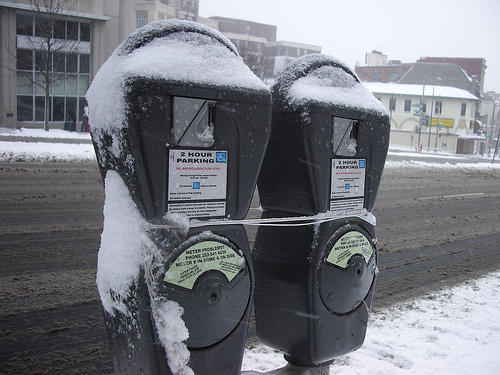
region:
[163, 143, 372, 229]
the stickers are white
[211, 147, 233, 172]
the handicap sign is on the sticker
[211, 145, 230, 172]
the handicap sign is small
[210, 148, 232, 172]
the handicap sign is blue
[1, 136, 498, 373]
the road is very dirty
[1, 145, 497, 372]
the snow on the road is black and slushy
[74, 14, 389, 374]
the snow on the meters is white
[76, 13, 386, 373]
the snow is on the meters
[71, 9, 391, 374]
this is a meter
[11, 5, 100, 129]
the windows behind a tree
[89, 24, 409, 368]
Two grey parking meters by the road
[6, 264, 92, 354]
Dirt on top of the road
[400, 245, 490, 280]
A black road behind the parking meters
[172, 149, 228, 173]
The meter says 2 hour parking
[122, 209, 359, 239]
Strings holding the parking meters together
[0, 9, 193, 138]
A brown building in the background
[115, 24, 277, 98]
Snow on top of the machines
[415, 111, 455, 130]
A yellow sign on the building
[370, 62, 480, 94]
Brown roof of the building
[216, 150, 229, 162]
A blue handicapped sign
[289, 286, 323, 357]
edge of a post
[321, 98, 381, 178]
part of a poster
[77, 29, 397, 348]
There is snow on the meters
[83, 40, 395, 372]
There are two meters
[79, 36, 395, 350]
The meters are black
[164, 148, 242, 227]
White sticker on the meter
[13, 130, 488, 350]
The road is covered in brown slush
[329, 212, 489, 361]
There is snow on the side of the road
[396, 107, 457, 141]
Yellow sign on building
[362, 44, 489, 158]
Building has a black roof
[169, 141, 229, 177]
Words say 2 Hour Parking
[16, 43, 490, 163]
Large buildings on the other side of the street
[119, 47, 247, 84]
Snow on top of parking meter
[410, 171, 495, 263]
Muddy snow in the road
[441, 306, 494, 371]
White snow next to the road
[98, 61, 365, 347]
Two black parking meters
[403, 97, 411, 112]
Black window on white building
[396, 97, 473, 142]
White building behind parking meters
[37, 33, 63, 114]
Tree in front of gray building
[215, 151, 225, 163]
Handicap symbol on parking meter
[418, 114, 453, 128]
Yellow banner on the building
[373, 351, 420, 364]
Footprint in the snow